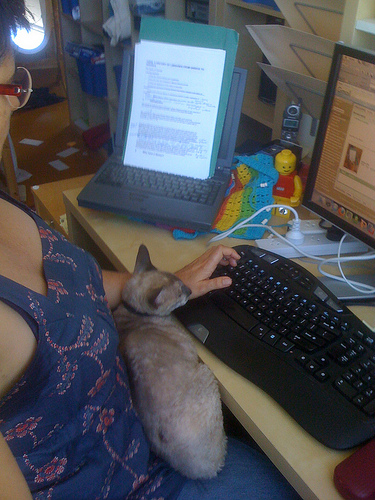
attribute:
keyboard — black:
[173, 244, 374, 451]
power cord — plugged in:
[206, 203, 374, 295]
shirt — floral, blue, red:
[0, 190, 189, 498]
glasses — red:
[0, 64, 34, 110]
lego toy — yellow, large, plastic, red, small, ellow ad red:
[266, 148, 301, 219]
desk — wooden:
[62, 155, 372, 498]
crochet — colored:
[171, 149, 279, 242]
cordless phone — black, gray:
[279, 96, 304, 147]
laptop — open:
[77, 45, 247, 234]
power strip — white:
[253, 233, 369, 258]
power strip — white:
[289, 218, 334, 234]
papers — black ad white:
[122, 37, 227, 180]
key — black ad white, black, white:
[263, 329, 279, 346]